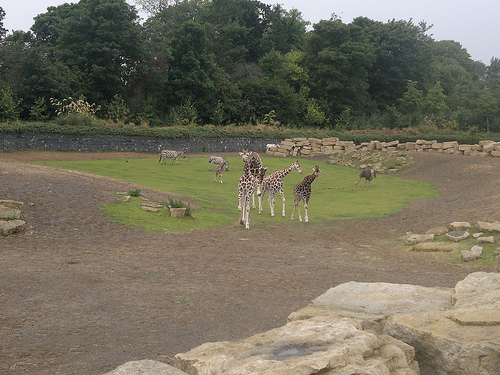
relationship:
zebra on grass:
[157, 149, 186, 165] [29, 153, 436, 238]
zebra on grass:
[208, 155, 231, 172] [29, 153, 436, 238]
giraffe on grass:
[214, 159, 229, 183] [29, 153, 436, 238]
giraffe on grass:
[241, 147, 263, 170] [29, 153, 436, 238]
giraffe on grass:
[237, 165, 268, 229] [29, 153, 436, 238]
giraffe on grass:
[259, 160, 303, 217] [29, 153, 436, 238]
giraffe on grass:
[291, 165, 323, 222] [29, 153, 436, 238]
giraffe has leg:
[259, 160, 303, 217] [279, 188, 287, 219]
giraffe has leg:
[259, 160, 303, 217] [269, 188, 275, 219]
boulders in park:
[281, 134, 397, 169] [16, 87, 471, 339]